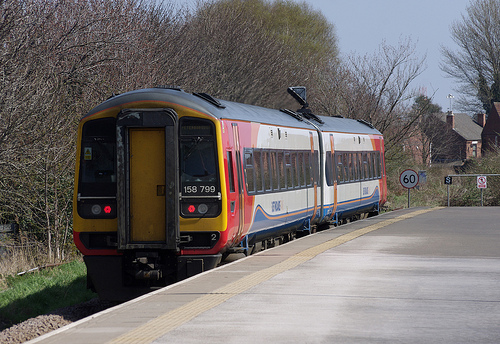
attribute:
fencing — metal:
[441, 170, 495, 200]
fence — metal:
[446, 172, 499, 206]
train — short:
[51, 81, 400, 301]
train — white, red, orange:
[72, 78, 385, 295]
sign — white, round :
[397, 167, 419, 190]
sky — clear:
[367, 1, 409, 45]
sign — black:
[444, 173, 457, 186]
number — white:
[445, 173, 455, 186]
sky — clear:
[349, 4, 411, 41]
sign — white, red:
[473, 167, 489, 194]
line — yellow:
[219, 204, 420, 309]